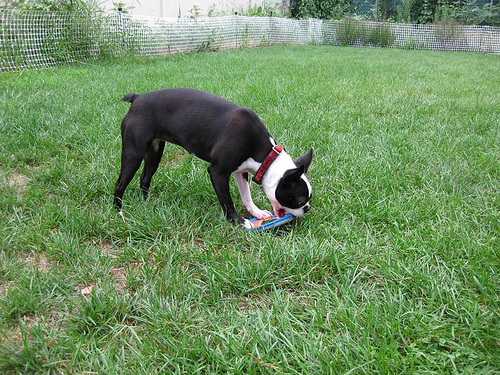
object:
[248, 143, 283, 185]
red collar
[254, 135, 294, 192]
dog's neck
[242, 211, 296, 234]
frisbee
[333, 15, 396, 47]
weeds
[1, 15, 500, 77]
fence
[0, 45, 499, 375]
grass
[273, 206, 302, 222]
mouth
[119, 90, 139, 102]
bob tail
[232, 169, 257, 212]
front leg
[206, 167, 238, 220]
front leg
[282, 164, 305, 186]
ear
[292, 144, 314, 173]
ear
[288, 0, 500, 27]
wall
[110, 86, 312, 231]
dog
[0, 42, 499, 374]
backyard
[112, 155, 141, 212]
leg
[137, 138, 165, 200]
leg